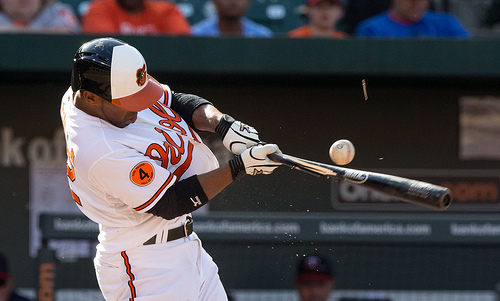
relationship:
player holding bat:
[41, 29, 337, 298] [267, 143, 461, 213]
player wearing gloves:
[41, 29, 337, 298] [226, 112, 283, 184]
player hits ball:
[41, 29, 337, 298] [327, 136, 356, 162]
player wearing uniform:
[41, 29, 337, 298] [40, 89, 234, 286]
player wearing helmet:
[41, 29, 337, 298] [58, 41, 169, 129]